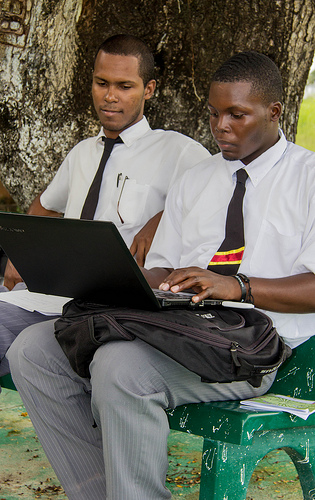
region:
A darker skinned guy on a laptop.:
[6, 55, 313, 499]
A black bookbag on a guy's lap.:
[53, 296, 294, 386]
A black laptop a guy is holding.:
[1, 210, 254, 311]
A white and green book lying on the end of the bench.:
[239, 392, 314, 418]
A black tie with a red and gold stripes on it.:
[206, 169, 251, 272]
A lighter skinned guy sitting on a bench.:
[0, 33, 211, 373]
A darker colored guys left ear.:
[269, 100, 282, 122]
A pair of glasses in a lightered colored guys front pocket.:
[116, 175, 132, 224]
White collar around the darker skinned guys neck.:
[219, 127, 286, 185]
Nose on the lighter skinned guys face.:
[102, 82, 119, 102]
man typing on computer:
[0, 51, 312, 305]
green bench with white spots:
[0, 328, 314, 498]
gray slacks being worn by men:
[1, 299, 280, 498]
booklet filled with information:
[236, 390, 313, 419]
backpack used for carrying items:
[61, 293, 300, 390]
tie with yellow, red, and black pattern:
[203, 167, 250, 281]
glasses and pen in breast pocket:
[106, 169, 146, 224]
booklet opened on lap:
[0, 282, 81, 318]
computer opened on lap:
[0, 202, 241, 313]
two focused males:
[87, 34, 292, 161]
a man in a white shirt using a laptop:
[0, 48, 313, 496]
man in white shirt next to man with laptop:
[0, 32, 207, 367]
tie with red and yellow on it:
[207, 168, 249, 268]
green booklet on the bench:
[238, 391, 310, 418]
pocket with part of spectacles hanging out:
[108, 171, 144, 220]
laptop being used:
[0, 212, 253, 306]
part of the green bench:
[171, 333, 312, 496]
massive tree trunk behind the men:
[0, 0, 312, 210]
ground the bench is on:
[0, 387, 312, 495]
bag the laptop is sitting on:
[52, 301, 289, 385]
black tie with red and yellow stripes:
[202, 166, 245, 272]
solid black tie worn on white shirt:
[75, 136, 118, 219]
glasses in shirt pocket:
[113, 171, 127, 225]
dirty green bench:
[2, 332, 313, 497]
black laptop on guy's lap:
[0, 210, 262, 309]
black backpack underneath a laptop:
[52, 291, 291, 387]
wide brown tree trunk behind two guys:
[0, 0, 313, 231]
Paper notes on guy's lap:
[0, 287, 72, 316]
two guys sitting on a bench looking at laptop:
[0, 32, 312, 498]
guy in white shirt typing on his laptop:
[2, 50, 313, 498]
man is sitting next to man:
[2, 35, 209, 376]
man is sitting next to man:
[5, 49, 311, 494]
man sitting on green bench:
[2, 35, 209, 375]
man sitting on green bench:
[4, 48, 310, 493]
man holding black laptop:
[1, 207, 251, 312]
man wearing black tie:
[205, 167, 246, 273]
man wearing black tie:
[78, 135, 123, 217]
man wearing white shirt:
[1, 34, 208, 259]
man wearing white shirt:
[145, 46, 311, 345]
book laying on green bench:
[239, 391, 313, 421]